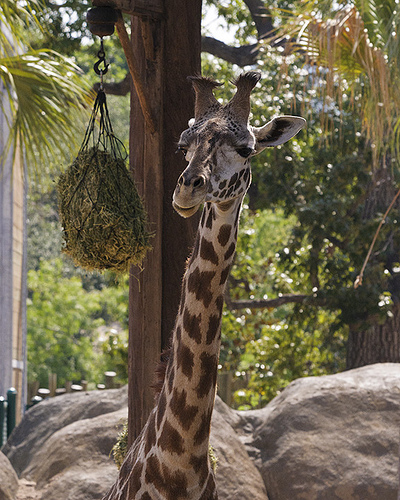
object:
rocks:
[258, 357, 400, 497]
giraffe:
[104, 73, 307, 499]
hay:
[56, 147, 154, 278]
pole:
[97, 0, 204, 460]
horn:
[186, 75, 218, 115]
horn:
[226, 72, 260, 121]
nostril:
[176, 175, 186, 187]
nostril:
[193, 177, 204, 190]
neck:
[147, 195, 257, 459]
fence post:
[6, 387, 18, 432]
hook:
[91, 49, 113, 77]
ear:
[255, 114, 308, 152]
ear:
[185, 117, 197, 127]